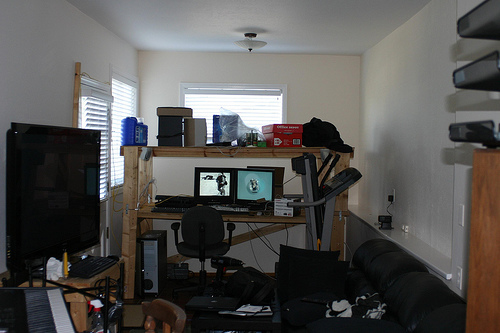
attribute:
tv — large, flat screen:
[6, 116, 101, 278]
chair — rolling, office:
[169, 200, 236, 295]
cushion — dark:
[283, 245, 360, 303]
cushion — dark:
[360, 243, 406, 303]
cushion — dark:
[402, 280, 452, 330]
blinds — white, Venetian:
[80, 78, 110, 199]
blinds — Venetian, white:
[108, 71, 146, 190]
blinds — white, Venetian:
[180, 83, 290, 155]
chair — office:
[171, 202, 244, 300]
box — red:
[270, 120, 306, 149]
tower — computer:
[135, 224, 166, 299]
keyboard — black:
[69, 253, 120, 277]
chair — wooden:
[118, 292, 192, 331]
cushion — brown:
[353, 235, 422, 305]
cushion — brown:
[403, 270, 464, 330]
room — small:
[5, 2, 471, 319]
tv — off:
[6, 115, 109, 297]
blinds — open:
[176, 80, 294, 141]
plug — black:
[384, 188, 393, 208]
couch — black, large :
[259, 232, 472, 329]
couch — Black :
[275, 229, 487, 329]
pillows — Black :
[254, 231, 360, 323]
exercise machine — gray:
[286, 148, 362, 258]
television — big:
[0, 118, 104, 270]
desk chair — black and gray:
[166, 205, 236, 293]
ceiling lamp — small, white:
[232, 25, 267, 53]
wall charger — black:
[384, 191, 395, 204]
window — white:
[79, 74, 115, 129]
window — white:
[177, 78, 285, 123]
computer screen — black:
[194, 165, 236, 199]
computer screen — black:
[193, 164, 235, 204]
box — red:
[258, 120, 300, 147]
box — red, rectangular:
[260, 121, 305, 146]